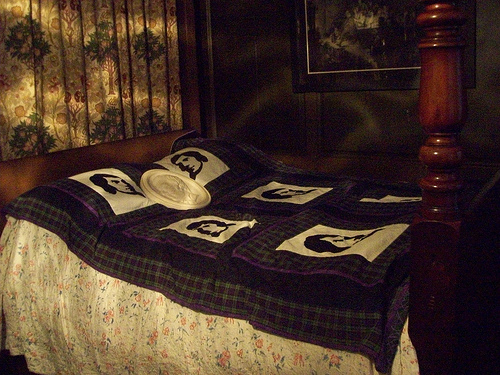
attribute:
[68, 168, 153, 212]
picture — white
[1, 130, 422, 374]
bed — here, brown, wooden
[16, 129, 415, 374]
blanket — large, purple, green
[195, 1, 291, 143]
wall — here, dark, wooden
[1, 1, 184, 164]
curtian — here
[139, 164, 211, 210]
coin — white, large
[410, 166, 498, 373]
headboard — wooden, brown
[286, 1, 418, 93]
painting — black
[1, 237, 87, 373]
blanket — white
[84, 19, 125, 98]
tree — green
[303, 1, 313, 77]
line — white